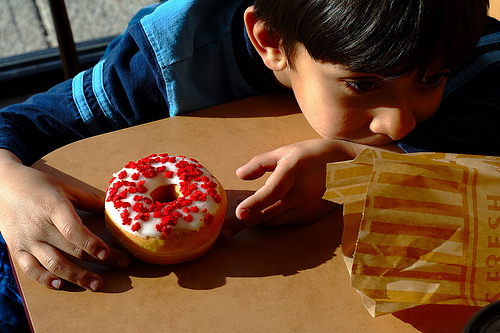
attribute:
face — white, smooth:
[273, 19, 450, 164]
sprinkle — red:
[163, 208, 184, 232]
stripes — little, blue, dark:
[60, 65, 127, 132]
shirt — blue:
[1, 17, 482, 283]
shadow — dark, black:
[199, 252, 354, 295]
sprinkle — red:
[175, 161, 206, 197]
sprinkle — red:
[129, 222, 141, 233]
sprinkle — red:
[190, 204, 201, 214]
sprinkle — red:
[106, 147, 222, 227]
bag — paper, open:
[308, 145, 498, 308]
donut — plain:
[102, 152, 227, 265]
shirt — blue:
[0, 0, 293, 161]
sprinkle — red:
[112, 183, 118, 204]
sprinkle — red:
[159, 197, 174, 229]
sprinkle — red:
[186, 178, 204, 221]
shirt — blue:
[63, 7, 209, 97]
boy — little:
[138, 17, 466, 142]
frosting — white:
[124, 212, 161, 244]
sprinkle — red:
[178, 206, 185, 214]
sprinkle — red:
[183, 173, 204, 203]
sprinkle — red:
[119, 169, 136, 205]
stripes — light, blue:
[56, 55, 98, 133]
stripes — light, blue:
[85, 47, 135, 122]